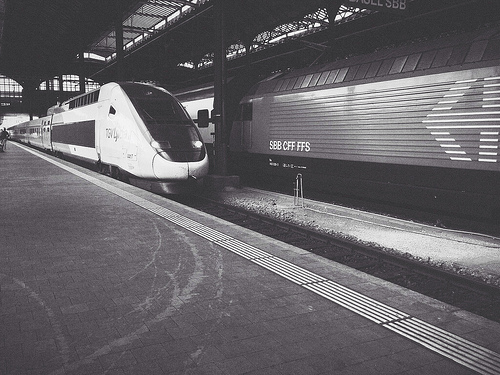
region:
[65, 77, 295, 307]
the train is white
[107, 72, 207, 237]
the train is white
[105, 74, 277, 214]
the train hood is black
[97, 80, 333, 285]
the train hood is black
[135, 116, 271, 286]
the train hood is black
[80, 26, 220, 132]
the train hood is black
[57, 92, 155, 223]
the window is black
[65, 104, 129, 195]
the window is black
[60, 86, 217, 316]
the window is black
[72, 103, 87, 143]
the window is black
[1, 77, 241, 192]
Passenger train in a terminal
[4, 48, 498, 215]
Two trains in a terminal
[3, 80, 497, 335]
Train on a railroad track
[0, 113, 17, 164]
People waiting for a train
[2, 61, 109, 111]
Windows in a train station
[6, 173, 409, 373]
Floor at a train station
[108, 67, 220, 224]
Windshield on a train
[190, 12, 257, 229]
Support beam in a train station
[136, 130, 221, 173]
Headlights on a train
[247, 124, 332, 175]
Letters on the side of a train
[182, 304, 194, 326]
white stains on the floor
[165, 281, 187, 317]
white stains on the floor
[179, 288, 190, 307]
white stains on the floor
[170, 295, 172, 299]
white stains on the floor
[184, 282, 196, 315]
white stains on the floor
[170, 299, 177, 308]
white stains on the floor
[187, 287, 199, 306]
white stains on the floor